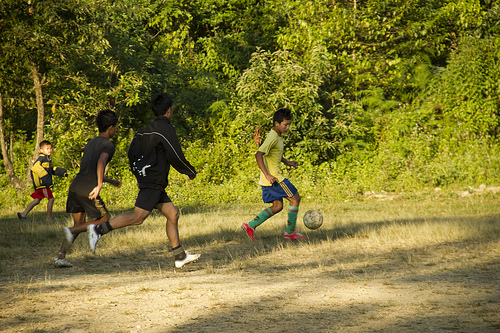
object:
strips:
[42, 189, 48, 198]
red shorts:
[30, 187, 53, 200]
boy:
[86, 93, 201, 267]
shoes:
[173, 252, 204, 268]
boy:
[241, 108, 302, 243]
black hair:
[273, 108, 293, 126]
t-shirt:
[256, 130, 285, 186]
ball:
[302, 210, 323, 231]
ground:
[0, 188, 500, 333]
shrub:
[0, 0, 500, 194]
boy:
[52, 109, 119, 266]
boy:
[16, 139, 67, 221]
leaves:
[300, 0, 500, 186]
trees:
[189, 0, 498, 186]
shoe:
[241, 222, 257, 242]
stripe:
[262, 209, 271, 218]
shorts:
[64, 188, 112, 217]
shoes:
[280, 231, 307, 240]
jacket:
[29, 154, 68, 188]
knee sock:
[286, 206, 301, 235]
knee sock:
[249, 207, 274, 231]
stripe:
[288, 209, 299, 213]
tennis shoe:
[84, 223, 99, 251]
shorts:
[261, 178, 297, 204]